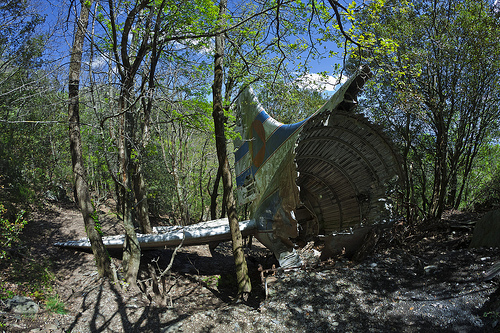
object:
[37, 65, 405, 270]
airplane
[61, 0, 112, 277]
woods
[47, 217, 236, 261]
tail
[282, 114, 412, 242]
crashed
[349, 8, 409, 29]
leaves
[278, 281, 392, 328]
ground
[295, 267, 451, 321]
shadow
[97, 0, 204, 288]
tree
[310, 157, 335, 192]
inside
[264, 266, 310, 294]
dirt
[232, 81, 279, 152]
wing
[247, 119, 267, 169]
drawing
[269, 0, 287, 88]
thin branches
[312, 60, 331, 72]
sky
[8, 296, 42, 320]
rock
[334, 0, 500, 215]
trees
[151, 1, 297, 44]
branches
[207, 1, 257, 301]
long trunks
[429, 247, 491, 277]
rocks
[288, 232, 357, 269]
crash